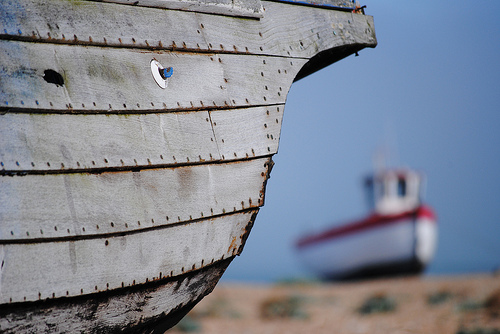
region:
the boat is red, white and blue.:
[286, 165, 453, 288]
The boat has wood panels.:
[24, 11, 280, 318]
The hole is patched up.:
[145, 51, 190, 99]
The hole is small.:
[33, 53, 75, 95]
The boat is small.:
[307, 149, 467, 282]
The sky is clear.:
[392, 23, 474, 155]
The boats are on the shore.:
[43, 23, 486, 325]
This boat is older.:
[18, 8, 373, 332]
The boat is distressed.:
[23, 8, 383, 320]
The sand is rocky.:
[228, 281, 339, 328]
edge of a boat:
[137, 1, 419, 294]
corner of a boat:
[152, 5, 397, 262]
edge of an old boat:
[154, 1, 439, 269]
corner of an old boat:
[112, 0, 435, 279]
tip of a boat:
[111, 0, 399, 272]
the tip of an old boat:
[140, 0, 423, 267]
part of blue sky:
[378, 1, 491, 145]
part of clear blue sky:
[375, 2, 492, 140]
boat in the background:
[278, 151, 469, 293]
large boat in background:
[282, 136, 472, 299]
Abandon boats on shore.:
[98, 16, 383, 332]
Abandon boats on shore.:
[69, 82, 466, 266]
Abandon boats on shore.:
[110, 175, 455, 261]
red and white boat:
[333, 152, 447, 265]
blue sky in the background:
[403, 99, 475, 167]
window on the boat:
[381, 170, 420, 208]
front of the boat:
[175, 92, 296, 202]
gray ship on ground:
[47, 107, 243, 286]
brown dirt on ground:
[280, 281, 385, 324]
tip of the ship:
[329, 6, 404, 69]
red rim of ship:
[312, 203, 429, 242]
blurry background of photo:
[290, 28, 492, 308]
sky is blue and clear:
[399, 47, 475, 172]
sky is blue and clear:
[336, 154, 496, 304]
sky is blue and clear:
[313, 92, 458, 208]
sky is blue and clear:
[299, 108, 414, 254]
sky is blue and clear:
[355, 150, 490, 242]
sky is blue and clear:
[228, 52, 485, 257]